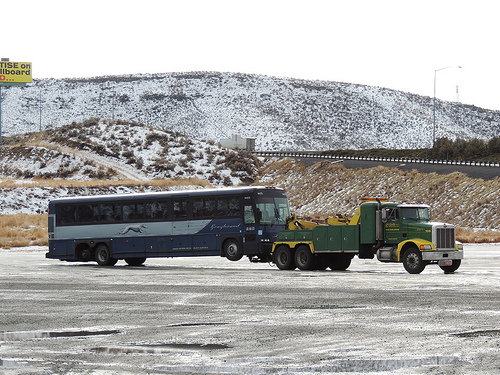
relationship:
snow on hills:
[274, 299, 359, 339] [144, 54, 377, 104]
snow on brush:
[14, 91, 246, 186] [35, 118, 261, 182]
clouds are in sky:
[304, 19, 394, 67] [72, 3, 225, 66]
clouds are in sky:
[0, 0, 498, 109] [9, 9, 497, 94]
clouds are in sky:
[0, 0, 498, 109] [4, 6, 497, 128]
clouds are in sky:
[0, 0, 498, 109] [136, 3, 447, 64]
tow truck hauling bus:
[269, 197, 464, 275] [37, 173, 294, 263]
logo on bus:
[115, 224, 147, 234] [38, 188, 284, 259]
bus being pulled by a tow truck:
[38, 179, 284, 269] [276, 192, 472, 281]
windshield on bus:
[243, 192, 293, 228] [46, 187, 290, 266]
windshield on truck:
[397, 202, 431, 219] [272, 196, 463, 273]